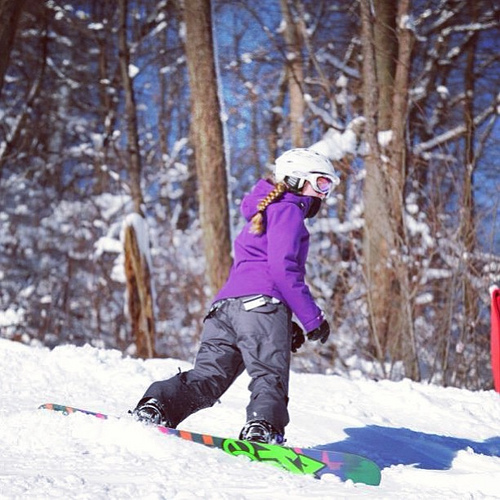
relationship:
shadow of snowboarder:
[332, 405, 498, 480] [189, 117, 391, 496]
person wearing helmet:
[126, 147, 338, 444] [270, 145, 342, 198]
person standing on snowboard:
[126, 147, 338, 444] [39, 400, 381, 488]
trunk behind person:
[183, 0, 233, 301] [126, 147, 338, 444]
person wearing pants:
[126, 147, 338, 444] [144, 297, 299, 442]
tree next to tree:
[460, 3, 497, 354] [426, 107, 451, 302]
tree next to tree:
[180, 1, 235, 296] [116, 2, 156, 359]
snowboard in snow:
[39, 400, 381, 488] [9, 352, 444, 472]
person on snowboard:
[126, 147, 338, 444] [39, 400, 381, 488]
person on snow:
[126, 147, 338, 444] [0, 330, 484, 500]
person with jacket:
[126, 147, 338, 444] [221, 186, 316, 299]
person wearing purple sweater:
[126, 147, 338, 444] [209, 173, 326, 333]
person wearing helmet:
[126, 147, 338, 444] [269, 145, 341, 203]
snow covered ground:
[14, 330, 485, 480] [18, 333, 484, 488]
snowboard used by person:
[39, 400, 381, 488] [126, 147, 338, 444]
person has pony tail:
[126, 147, 338, 444] [246, 174, 288, 239]